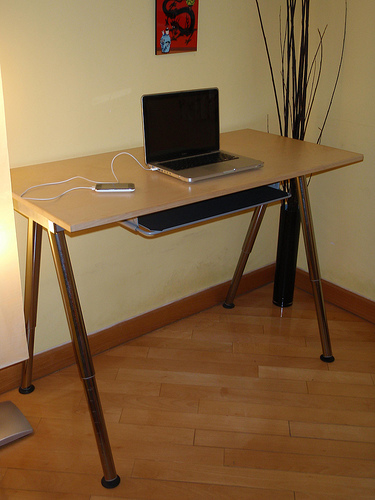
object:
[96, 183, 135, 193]
cell phone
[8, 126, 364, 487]
table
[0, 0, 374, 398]
wall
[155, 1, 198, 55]
artwork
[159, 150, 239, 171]
keyboard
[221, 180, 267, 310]
leg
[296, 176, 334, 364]
leg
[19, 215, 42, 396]
leg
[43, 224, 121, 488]
leg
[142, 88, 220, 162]
screen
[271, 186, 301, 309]
pot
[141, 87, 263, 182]
laptop